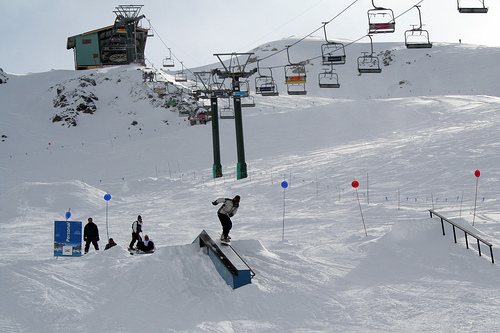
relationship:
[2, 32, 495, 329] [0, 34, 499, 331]
hillside covered in snow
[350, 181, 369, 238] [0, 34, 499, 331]
circle stick in snow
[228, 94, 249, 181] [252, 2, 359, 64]
metal pole holding up ski-lift wire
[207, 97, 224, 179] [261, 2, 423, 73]
metal pole holding up ski-lift wire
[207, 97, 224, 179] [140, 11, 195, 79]
metal pole holding up ski-lift wire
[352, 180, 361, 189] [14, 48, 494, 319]
red circle stick in snow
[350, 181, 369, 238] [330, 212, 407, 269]
circle stick in snow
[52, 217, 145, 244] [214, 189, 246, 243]
people watching snowboarder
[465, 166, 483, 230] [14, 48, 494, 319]
circle stick in snow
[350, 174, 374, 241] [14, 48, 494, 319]
circle stick in snow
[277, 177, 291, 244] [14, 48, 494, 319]
circle stick in snow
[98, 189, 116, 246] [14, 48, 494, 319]
circle stick in snow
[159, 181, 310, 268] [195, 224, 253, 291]
snowboarder on ramp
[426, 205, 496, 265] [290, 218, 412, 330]
fence in snow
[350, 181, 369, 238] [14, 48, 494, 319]
circle stick in snow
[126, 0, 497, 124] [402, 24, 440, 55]
ski lift has chair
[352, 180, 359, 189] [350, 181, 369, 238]
red circle on circle stick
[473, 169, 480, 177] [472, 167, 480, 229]
red circle on pole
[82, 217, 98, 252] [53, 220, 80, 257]
person next sign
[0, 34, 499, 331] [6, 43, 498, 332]
snow on ground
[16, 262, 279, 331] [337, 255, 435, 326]
snow on ground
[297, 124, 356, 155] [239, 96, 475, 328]
snow on ground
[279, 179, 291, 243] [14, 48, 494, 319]
circle stick on snow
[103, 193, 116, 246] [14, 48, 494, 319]
circle stick on snow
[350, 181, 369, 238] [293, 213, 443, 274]
circle stick on ground